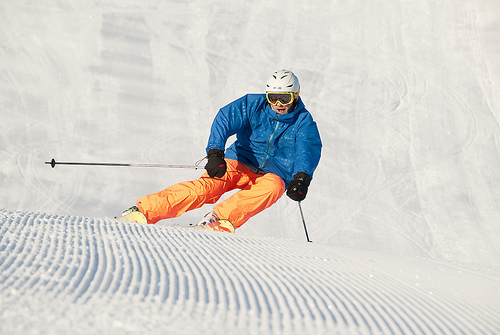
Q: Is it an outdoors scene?
A: Yes, it is outdoors.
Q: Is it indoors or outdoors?
A: It is outdoors.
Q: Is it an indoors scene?
A: No, it is outdoors.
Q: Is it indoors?
A: No, it is outdoors.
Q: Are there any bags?
A: No, there are no bags.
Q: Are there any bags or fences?
A: No, there are no bags or fences.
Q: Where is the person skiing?
A: The person is skiing in the snow.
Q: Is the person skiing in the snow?
A: Yes, the person is skiing in the snow.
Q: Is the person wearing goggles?
A: Yes, the person is wearing goggles.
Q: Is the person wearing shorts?
A: No, the person is wearing goggles.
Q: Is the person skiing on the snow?
A: Yes, the person is skiing on the snow.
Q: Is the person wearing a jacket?
A: Yes, the person is wearing a jacket.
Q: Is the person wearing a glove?
A: No, the person is wearing a jacket.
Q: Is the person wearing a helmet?
A: Yes, the person is wearing a helmet.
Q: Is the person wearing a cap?
A: No, the person is wearing a helmet.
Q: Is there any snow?
A: Yes, there is snow.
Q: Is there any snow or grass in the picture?
A: Yes, there is snow.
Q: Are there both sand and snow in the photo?
A: No, there is snow but no sand.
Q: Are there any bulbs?
A: No, there are no bulbs.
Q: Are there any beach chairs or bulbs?
A: No, there are no bulbs or beach chairs.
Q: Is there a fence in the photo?
A: No, there are no fences.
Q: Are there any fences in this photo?
A: No, there are no fences.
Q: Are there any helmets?
A: Yes, there is a helmet.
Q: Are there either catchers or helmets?
A: Yes, there is a helmet.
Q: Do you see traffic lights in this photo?
A: No, there are no traffic lights.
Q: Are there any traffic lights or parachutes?
A: No, there are no traffic lights or parachutes.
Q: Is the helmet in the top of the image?
A: Yes, the helmet is in the top of the image.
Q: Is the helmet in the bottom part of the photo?
A: No, the helmet is in the top of the image.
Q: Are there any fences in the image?
A: No, there are no fences.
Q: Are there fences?
A: No, there are no fences.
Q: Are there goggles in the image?
A: Yes, there are goggles.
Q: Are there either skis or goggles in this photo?
A: Yes, there are goggles.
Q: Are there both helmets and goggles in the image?
A: Yes, there are both goggles and a helmet.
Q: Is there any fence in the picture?
A: No, there are no fences.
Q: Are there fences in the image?
A: No, there are no fences.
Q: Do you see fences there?
A: No, there are no fences.